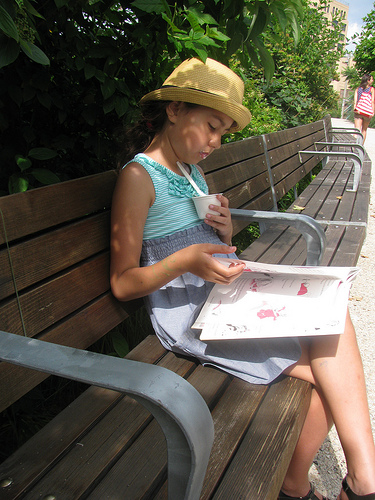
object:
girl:
[108, 56, 374, 496]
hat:
[137, 56, 252, 132]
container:
[189, 195, 223, 220]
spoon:
[170, 160, 208, 196]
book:
[188, 258, 357, 343]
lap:
[191, 307, 217, 345]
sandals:
[334, 478, 372, 500]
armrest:
[226, 207, 325, 266]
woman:
[353, 76, 374, 145]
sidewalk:
[324, 117, 373, 499]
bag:
[355, 91, 373, 121]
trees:
[340, 1, 374, 91]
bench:
[0, 120, 371, 498]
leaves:
[251, 36, 275, 88]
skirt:
[139, 222, 303, 385]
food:
[203, 155, 208, 161]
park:
[1, 1, 373, 500]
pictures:
[246, 276, 269, 298]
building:
[307, 0, 349, 92]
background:
[0, 0, 374, 499]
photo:
[1, 0, 374, 499]